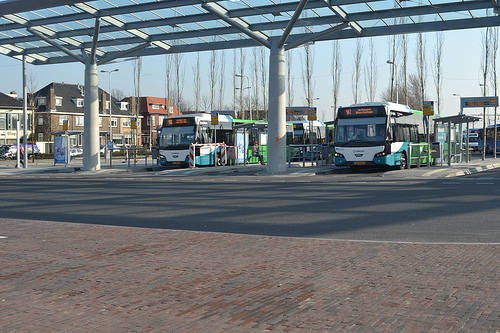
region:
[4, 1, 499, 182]
City bus loading terminal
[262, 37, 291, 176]
Cement pylon supporting terminal roof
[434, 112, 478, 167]
Metal framed bus stop shelter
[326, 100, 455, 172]
City bus parked at terminal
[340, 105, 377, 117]
Digital route information sign on bus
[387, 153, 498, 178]
Cement bus passenger platform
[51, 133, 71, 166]
Advertisement placard on bus passenger shelter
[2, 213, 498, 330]
Brick sidewalk across from bus terminal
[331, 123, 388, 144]
Windshield of city bus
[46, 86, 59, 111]
Brick chimney on building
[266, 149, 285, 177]
part of a pillar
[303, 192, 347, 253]
part of a shade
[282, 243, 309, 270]
part of a floor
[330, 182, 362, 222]
part of a shade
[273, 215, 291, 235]
par tof a road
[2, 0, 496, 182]
Structure of metal framework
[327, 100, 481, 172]
Bus parked next to a shade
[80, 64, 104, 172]
Thick white metal pillar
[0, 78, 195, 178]
Buildings in a line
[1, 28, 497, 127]
Clear blue sky background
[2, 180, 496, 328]
Smooth tarmaced open ground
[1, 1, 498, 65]
Long metal frame with transparent roof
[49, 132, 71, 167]
Advertisement board on the ground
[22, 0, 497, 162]
Group of tall thin trees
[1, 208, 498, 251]
Line between tarmaced road and brick pavement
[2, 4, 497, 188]
Bus stop with two buses.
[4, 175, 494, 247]
Road near a bus stop.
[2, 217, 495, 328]
Red brick sidewalk.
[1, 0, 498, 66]
Roof of a bus stop.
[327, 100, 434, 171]
Bus sitting at a bus station.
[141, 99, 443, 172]
Three buses at a bus stop.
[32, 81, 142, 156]
Brown brick house.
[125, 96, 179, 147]
House with a red roof.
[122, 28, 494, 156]
Row of trees behind buses.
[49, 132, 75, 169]
Sign on a sidewalk.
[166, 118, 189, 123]
The marquee display on the bus on the left.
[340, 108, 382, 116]
The marquee display of the bus on the right.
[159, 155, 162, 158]
The left headlight on the bus on the left.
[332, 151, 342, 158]
The left headlight on the bus on the right.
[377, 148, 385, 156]
The right headlight on the bus on the right.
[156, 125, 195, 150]
The front window of the bus on the left.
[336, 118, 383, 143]
The front window of the bus on the right.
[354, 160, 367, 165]
The yellow license plate on the bus on the right.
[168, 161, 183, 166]
The license plate on the bus on the left.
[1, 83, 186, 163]
The houses on the left.